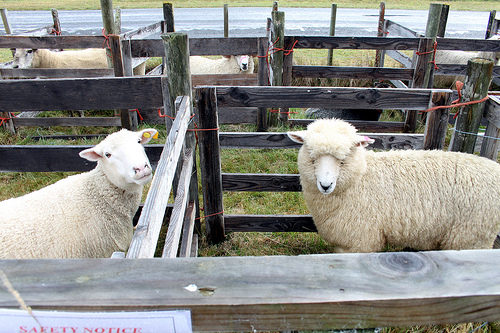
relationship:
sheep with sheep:
[288, 108, 500, 249] [0, 121, 164, 268]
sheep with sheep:
[151, 37, 253, 100] [9, 38, 154, 125]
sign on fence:
[3, 302, 193, 332] [4, 6, 499, 326]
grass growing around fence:
[6, 44, 491, 262] [4, 6, 499, 326]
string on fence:
[4, 17, 491, 238] [4, 6, 499, 326]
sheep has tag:
[0, 121, 164, 268] [141, 128, 162, 141]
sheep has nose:
[0, 121, 164, 268] [133, 160, 152, 174]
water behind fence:
[4, 8, 494, 52] [4, 6, 499, 326]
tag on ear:
[141, 128, 162, 141] [135, 125, 159, 147]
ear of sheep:
[135, 125, 159, 147] [0, 121, 164, 268]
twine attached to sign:
[1, 266, 42, 331] [3, 302, 193, 332]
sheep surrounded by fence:
[7, 17, 500, 267] [4, 6, 499, 326]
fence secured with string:
[4, 6, 499, 326] [4, 17, 491, 238]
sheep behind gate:
[301, 59, 395, 124] [282, 30, 426, 135]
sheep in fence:
[7, 17, 500, 267] [4, 6, 499, 326]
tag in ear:
[141, 128, 162, 141] [135, 125, 159, 147]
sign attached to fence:
[3, 302, 193, 332] [4, 6, 499, 326]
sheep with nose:
[288, 108, 500, 249] [316, 180, 335, 191]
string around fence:
[4, 17, 491, 238] [4, 6, 499, 326]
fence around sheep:
[4, 6, 499, 326] [7, 17, 500, 267]